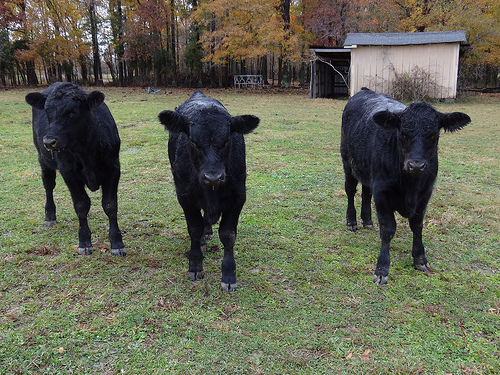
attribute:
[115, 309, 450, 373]
field — grassy